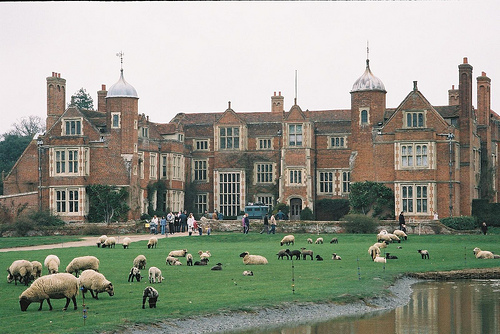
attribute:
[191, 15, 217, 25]
sky — white, day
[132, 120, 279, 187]
building — brown, brick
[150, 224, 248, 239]
people — standing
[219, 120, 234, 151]
window — large, white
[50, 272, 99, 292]
sheep — laying, baby, eating, black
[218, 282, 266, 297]
grass — green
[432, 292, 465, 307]
water — body, reflecting, brown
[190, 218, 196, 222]
shirt — white, blue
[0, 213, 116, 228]
fence — wire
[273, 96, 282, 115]
chimney — red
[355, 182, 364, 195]
bushes — green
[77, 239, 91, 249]
walkway — paved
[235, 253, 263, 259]
lamb — white, black